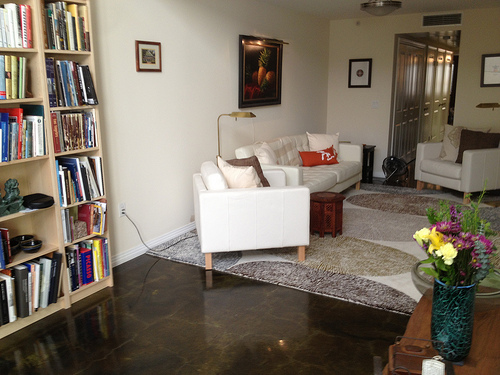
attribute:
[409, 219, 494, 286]
flowers — purple, silk, yellow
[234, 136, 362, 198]
sofa — here, white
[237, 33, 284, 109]
art — fruit painting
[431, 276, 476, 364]
vase — green, teal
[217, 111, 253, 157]
floor lamp — gold colored, here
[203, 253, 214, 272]
leg — wooden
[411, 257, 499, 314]
bowl — clear glass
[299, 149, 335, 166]
pillow — red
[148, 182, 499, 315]
area rug — oval designed, white, brown, here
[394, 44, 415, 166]
door — white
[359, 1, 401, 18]
ceiling light — here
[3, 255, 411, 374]
floor — dark, marble, here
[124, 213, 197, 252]
electrical wire — here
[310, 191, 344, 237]
end table — here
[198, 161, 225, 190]
cushion — white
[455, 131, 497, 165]
pillow — brown